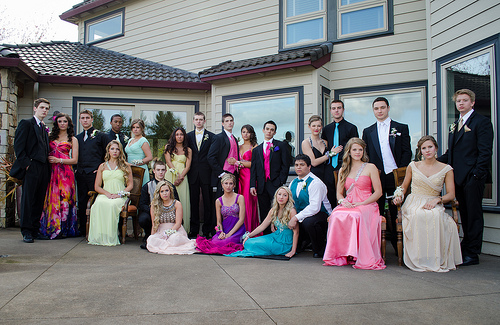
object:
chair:
[84, 165, 145, 244]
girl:
[194, 172, 247, 257]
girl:
[144, 180, 200, 256]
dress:
[236, 143, 263, 238]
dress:
[144, 199, 199, 256]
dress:
[161, 144, 191, 234]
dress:
[194, 193, 248, 254]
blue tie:
[329, 123, 340, 169]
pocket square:
[461, 125, 471, 132]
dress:
[86, 161, 129, 246]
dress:
[221, 216, 293, 258]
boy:
[431, 88, 494, 268]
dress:
[303, 135, 339, 251]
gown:
[298, 134, 339, 252]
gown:
[399, 161, 463, 273]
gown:
[321, 162, 386, 271]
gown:
[86, 160, 132, 247]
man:
[321, 99, 358, 171]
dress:
[37, 136, 81, 240]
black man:
[104, 114, 132, 244]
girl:
[36, 113, 81, 241]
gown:
[236, 143, 263, 239]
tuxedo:
[359, 119, 413, 181]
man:
[69, 109, 107, 237]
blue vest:
[288, 175, 313, 214]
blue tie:
[297, 178, 304, 182]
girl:
[390, 135, 463, 273]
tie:
[38, 122, 49, 141]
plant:
[144, 111, 188, 144]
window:
[438, 43, 496, 207]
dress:
[396, 161, 463, 272]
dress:
[321, 162, 386, 270]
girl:
[121, 117, 152, 239]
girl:
[300, 115, 343, 252]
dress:
[123, 136, 151, 214]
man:
[6, 94, 61, 236]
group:
[15, 90, 493, 270]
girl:
[320, 137, 386, 271]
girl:
[86, 139, 134, 246]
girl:
[161, 127, 193, 235]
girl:
[227, 124, 263, 239]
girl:
[222, 185, 299, 259]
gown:
[162, 148, 191, 234]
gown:
[37, 140, 81, 240]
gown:
[145, 199, 201, 255]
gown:
[193, 193, 249, 254]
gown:
[221, 216, 293, 258]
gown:
[123, 136, 151, 215]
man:
[359, 97, 413, 257]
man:
[246, 120, 293, 236]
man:
[199, 113, 240, 239]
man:
[12, 96, 53, 241]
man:
[213, 114, 244, 190]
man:
[184, 108, 222, 225]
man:
[69, 103, 109, 199]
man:
[434, 87, 496, 266]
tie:
[455, 118, 462, 132]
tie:
[378, 121, 389, 142]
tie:
[263, 141, 272, 166]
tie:
[194, 129, 206, 147]